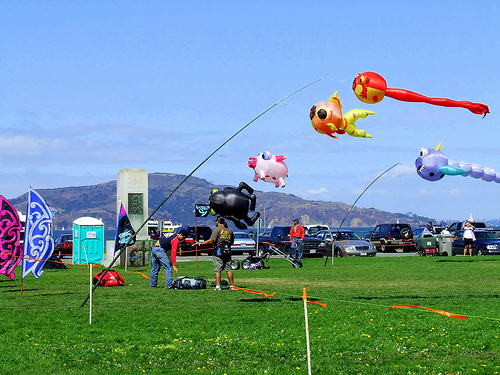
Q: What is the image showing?
A: It is showing a field.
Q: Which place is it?
A: It is a field.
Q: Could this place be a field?
A: Yes, it is a field.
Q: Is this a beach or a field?
A: It is a field.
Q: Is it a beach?
A: No, it is a field.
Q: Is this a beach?
A: No, it is a field.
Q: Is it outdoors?
A: Yes, it is outdoors.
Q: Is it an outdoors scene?
A: Yes, it is outdoors.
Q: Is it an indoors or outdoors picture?
A: It is outdoors.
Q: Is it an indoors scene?
A: No, it is outdoors.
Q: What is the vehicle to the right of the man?
A: The vehicle is a car.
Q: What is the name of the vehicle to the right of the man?
A: The vehicle is a car.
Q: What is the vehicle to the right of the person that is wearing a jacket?
A: The vehicle is a car.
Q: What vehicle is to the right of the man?
A: The vehicle is a car.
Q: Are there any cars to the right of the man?
A: Yes, there is a car to the right of the man.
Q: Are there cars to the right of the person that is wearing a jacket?
A: Yes, there is a car to the right of the man.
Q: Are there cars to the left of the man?
A: No, the car is to the right of the man.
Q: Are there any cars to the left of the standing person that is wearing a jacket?
A: No, the car is to the right of the man.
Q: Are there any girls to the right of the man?
A: No, there is a car to the right of the man.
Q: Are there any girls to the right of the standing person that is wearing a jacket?
A: No, there is a car to the right of the man.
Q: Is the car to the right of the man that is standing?
A: Yes, the car is to the right of the man.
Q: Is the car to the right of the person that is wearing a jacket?
A: Yes, the car is to the right of the man.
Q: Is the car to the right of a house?
A: No, the car is to the right of the man.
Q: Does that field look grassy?
A: Yes, the field is grassy.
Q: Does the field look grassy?
A: Yes, the field is grassy.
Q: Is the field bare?
A: No, the field is grassy.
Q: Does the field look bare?
A: No, the field is grassy.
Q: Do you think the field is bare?
A: No, the field is grassy.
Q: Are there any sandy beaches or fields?
A: No, there is a field but it is grassy.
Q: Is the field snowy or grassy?
A: The field is grassy.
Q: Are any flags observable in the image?
A: Yes, there is a flag.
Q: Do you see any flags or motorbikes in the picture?
A: Yes, there is a flag.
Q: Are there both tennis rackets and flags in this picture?
A: No, there is a flag but no rackets.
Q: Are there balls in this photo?
A: No, there are no balls.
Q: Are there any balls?
A: No, there are no balls.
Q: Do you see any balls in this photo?
A: No, there are no balls.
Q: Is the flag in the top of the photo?
A: No, the flag is in the bottom of the image.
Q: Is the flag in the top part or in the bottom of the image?
A: The flag is in the bottom of the image.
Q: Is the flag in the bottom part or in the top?
A: The flag is in the bottom of the image.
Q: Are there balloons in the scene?
A: Yes, there is a balloon.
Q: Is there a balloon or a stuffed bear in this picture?
A: Yes, there is a balloon.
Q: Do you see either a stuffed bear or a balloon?
A: Yes, there is a balloon.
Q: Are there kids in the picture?
A: No, there are no kids.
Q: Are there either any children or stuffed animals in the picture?
A: No, there are no children or stuffed animals.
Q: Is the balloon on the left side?
A: No, the balloon is on the right of the image.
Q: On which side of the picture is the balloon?
A: The balloon is on the right of the image.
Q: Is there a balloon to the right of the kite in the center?
A: Yes, there is a balloon to the right of the kite.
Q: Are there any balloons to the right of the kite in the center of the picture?
A: Yes, there is a balloon to the right of the kite.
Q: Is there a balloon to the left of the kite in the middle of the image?
A: No, the balloon is to the right of the kite.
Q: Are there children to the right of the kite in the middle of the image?
A: No, there is a balloon to the right of the kite.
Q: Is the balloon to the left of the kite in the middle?
A: No, the balloon is to the right of the kite.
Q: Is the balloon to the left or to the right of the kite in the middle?
A: The balloon is to the right of the kite.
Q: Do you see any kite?
A: Yes, there is a kite.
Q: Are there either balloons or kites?
A: Yes, there is a kite.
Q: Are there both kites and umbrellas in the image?
A: No, there is a kite but no umbrellas.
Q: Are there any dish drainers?
A: No, there are no dish drainers.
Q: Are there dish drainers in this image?
A: No, there are no dish drainers.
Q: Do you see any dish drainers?
A: No, there are no dish drainers.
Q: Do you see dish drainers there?
A: No, there are no dish drainers.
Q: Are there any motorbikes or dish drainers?
A: No, there are no dish drainers or motorbikes.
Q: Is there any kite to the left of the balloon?
A: Yes, there is a kite to the left of the balloon.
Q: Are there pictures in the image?
A: No, there are no pictures.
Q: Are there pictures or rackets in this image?
A: No, there are no pictures or rackets.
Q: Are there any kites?
A: Yes, there is a kite.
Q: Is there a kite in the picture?
A: Yes, there is a kite.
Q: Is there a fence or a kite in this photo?
A: Yes, there is a kite.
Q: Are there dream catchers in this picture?
A: No, there are no dream catchers.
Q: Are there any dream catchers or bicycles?
A: No, there are no dream catchers or bicycles.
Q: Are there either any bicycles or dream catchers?
A: No, there are no dream catchers or bicycles.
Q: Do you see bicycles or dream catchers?
A: No, there are no dream catchers or bicycles.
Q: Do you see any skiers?
A: No, there are no skiers.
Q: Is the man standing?
A: Yes, the man is standing.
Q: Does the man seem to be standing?
A: Yes, the man is standing.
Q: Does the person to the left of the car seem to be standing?
A: Yes, the man is standing.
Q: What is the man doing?
A: The man is standing.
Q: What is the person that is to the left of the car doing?
A: The man is standing.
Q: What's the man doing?
A: The man is standing.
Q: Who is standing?
A: The man is standing.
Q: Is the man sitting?
A: No, the man is standing.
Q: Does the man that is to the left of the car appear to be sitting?
A: No, the man is standing.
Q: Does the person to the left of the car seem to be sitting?
A: No, the man is standing.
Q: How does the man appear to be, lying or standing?
A: The man is standing.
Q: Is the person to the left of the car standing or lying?
A: The man is standing.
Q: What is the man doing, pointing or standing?
A: The man is standing.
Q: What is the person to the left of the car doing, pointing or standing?
A: The man is standing.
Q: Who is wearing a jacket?
A: The man is wearing a jacket.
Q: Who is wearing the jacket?
A: The man is wearing a jacket.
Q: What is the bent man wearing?
A: The man is wearing a jacket.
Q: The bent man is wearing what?
A: The man is wearing a jacket.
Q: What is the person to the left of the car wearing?
A: The man is wearing a jacket.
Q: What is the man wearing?
A: The man is wearing a jacket.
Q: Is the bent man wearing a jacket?
A: Yes, the man is wearing a jacket.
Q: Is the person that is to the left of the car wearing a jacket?
A: Yes, the man is wearing a jacket.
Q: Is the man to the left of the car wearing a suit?
A: No, the man is wearing a jacket.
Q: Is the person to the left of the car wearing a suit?
A: No, the man is wearing a jacket.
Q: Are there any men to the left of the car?
A: Yes, there is a man to the left of the car.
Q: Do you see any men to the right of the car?
A: No, the man is to the left of the car.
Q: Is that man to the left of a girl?
A: No, the man is to the left of the car.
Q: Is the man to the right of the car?
A: No, the man is to the left of the car.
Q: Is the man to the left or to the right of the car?
A: The man is to the left of the car.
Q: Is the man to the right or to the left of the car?
A: The man is to the left of the car.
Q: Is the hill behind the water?
A: Yes, the hill is behind the water.